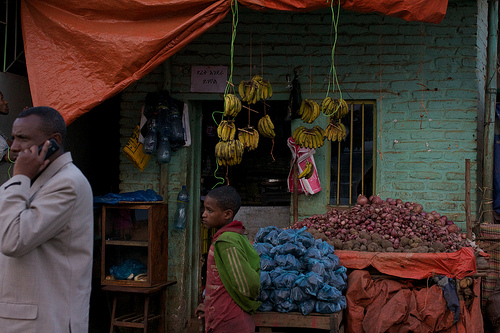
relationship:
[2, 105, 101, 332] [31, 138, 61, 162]
man holding phone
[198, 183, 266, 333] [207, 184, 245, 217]
boy has hair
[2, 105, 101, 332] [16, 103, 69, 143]
man has hair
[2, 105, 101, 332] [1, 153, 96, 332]
man wearing jacket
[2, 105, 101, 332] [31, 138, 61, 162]
man on phone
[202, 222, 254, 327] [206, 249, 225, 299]
shirt has decal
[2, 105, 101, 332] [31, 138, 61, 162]
man using phone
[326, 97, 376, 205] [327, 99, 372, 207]
window has bars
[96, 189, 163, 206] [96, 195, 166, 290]
bag on shelves